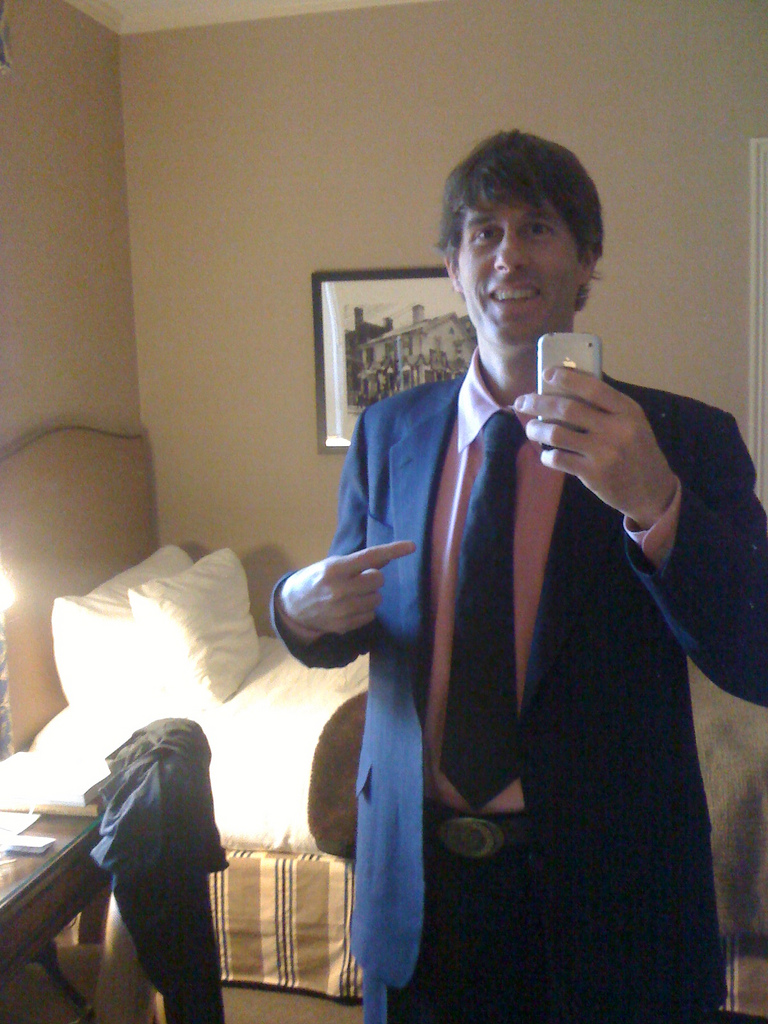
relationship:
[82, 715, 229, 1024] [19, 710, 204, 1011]
jacket is on the chair